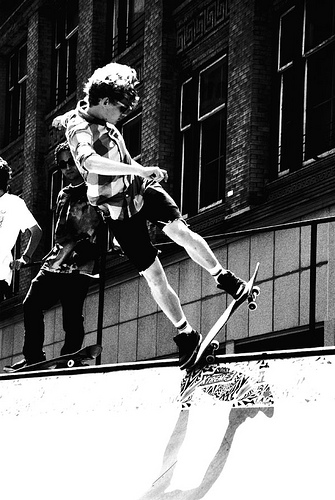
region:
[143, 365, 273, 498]
black and white shadow of skateboarder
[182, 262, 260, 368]
black and white skateboard with four wheels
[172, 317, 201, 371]
black skating shoe with white and black sock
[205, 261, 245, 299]
black skating shoe with white and black sock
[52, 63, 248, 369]
male skateboarder with black shorts and sunglasses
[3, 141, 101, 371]
male skateboarder with black pants and sunglasses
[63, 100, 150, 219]
black and white plaid short sleeved shirt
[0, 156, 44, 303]
male skateboarder with white tee shirt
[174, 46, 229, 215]
large multi-paned window on building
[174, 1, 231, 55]
decorative pattern on brick building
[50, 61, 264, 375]
one man doing trick on skateboard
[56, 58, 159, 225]
man wearing plaid short sleeved shirt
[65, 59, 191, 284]
man wearing dark shorts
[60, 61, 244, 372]
man wearing dark sneakers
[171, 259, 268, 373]
two sneakered feet on skateboard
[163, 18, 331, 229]
some rectangular shaped building windows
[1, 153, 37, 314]
partial view of man wearing white t shirt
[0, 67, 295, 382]
men enjoying skate park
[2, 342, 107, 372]
two feet on dark skateboard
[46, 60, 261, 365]
two men on skateboards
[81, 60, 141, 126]
Blonde young man's head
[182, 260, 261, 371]
Black and white pictured skate board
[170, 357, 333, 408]
Printed reflection on a skating wall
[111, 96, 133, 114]
Young man's sun glasses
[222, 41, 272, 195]
Brick wall on a building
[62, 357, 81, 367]
Wheel on a skate board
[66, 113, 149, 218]
Checkered young male's shirt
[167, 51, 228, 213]
Glass windows on a building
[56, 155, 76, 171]
Black male sun glasses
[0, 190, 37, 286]
Male's white t shirt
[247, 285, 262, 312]
wheels on front of skateboard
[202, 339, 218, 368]
wheels on back of skateboard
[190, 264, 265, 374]
skateboard on the ramp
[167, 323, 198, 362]
black shoe on right foot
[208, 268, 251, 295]
black shoe on left foot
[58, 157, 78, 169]
sunglasses on man's face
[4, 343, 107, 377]
skateboard being ridden on ramp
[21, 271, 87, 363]
black pants on man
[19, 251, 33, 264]
bracelet on man's left wrist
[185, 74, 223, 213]
window on the building